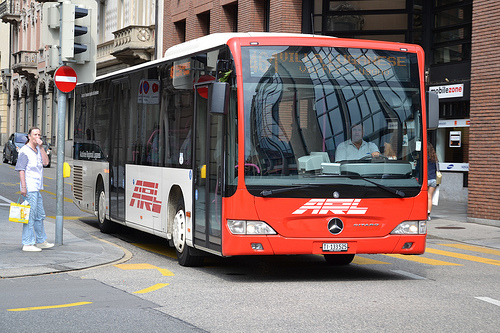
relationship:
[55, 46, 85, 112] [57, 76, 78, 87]
street sign that red and white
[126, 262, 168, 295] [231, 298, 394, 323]
yellow markings that are on street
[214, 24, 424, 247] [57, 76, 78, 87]
bus that red and white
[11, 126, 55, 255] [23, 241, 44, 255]
person wearing a white tennis shoe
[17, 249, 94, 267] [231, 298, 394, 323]
sidewalk next to street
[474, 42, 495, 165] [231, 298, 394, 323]
brick building next to street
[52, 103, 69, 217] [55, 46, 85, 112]
gray pole holding up street sign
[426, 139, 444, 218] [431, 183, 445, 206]
person carrying white bag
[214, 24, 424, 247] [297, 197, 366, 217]
bus with white logo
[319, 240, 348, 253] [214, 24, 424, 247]
license plate that on bus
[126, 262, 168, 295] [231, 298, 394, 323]
yellow markings on street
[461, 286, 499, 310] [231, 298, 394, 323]
white lines on street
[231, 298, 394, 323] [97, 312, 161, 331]
street that dark grey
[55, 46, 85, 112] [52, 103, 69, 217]
street sign on gray pole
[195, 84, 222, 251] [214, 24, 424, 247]
door on bus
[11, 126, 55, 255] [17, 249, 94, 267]
person standing on sidewalk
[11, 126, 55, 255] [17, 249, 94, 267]
person standing at sidewalk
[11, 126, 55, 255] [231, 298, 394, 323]
person standing on street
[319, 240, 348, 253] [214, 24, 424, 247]
license plate on bus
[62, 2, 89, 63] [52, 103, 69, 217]
traffic light on gray pole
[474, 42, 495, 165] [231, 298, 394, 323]
brick building close to street